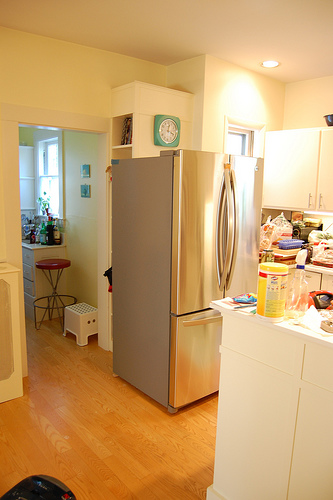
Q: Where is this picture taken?
A: In the kitchen.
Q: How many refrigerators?
A: Only one.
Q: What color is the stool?
A: Its red.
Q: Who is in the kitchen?
A: No one right now.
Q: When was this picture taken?
A: In the daytime.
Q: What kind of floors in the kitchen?
A: They are hardwood.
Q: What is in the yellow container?
A: Lysol wipes.